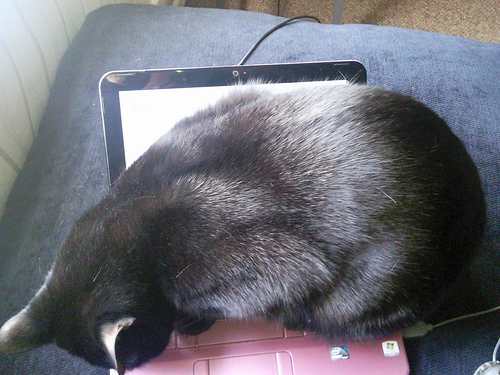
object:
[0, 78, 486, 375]
cat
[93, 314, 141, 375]
ear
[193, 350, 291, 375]
mouse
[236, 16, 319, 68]
power supply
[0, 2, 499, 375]
carpet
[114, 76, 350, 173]
laptop screen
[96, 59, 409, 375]
laptop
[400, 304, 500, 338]
cord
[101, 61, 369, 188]
monitor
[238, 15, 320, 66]
power cord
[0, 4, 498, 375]
pillow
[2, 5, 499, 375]
couch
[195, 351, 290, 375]
touch pad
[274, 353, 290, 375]
buttons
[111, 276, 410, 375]
keyboard